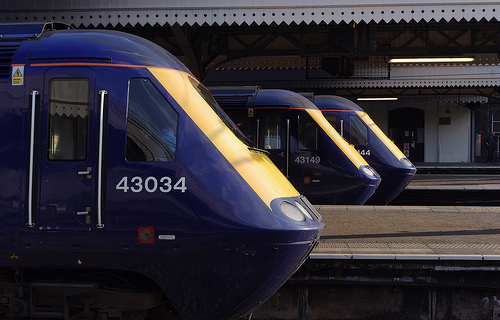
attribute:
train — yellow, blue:
[4, 18, 326, 318]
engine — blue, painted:
[0, 22, 323, 318]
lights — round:
[273, 196, 315, 221]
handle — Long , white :
[93, 88, 106, 229]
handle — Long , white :
[25, 90, 37, 225]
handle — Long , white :
[282, 117, 292, 177]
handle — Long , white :
[252, 115, 262, 146]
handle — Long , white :
[336, 110, 345, 135]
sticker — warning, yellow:
[106, 63, 310, 253]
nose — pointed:
[212, 182, 345, 294]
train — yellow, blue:
[209, 73, 376, 225]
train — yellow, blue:
[316, 93, 414, 210]